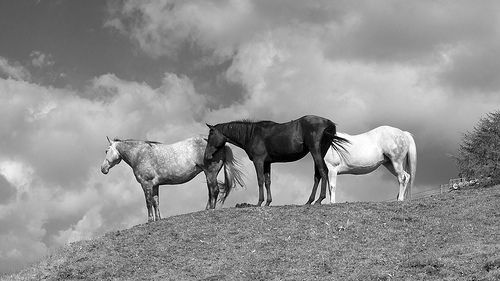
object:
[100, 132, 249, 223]
horse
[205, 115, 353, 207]
horse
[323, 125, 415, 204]
horse